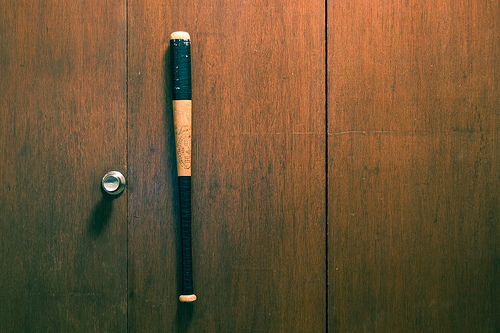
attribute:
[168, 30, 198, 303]
baseball — wooden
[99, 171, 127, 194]
object — metal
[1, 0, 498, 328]
table — wooden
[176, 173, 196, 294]
tape — black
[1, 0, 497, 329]
wall — wood panelling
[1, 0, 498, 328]
wood — burned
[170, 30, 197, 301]
wood — stamped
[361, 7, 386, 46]
specks — brown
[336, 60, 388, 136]
specks — brown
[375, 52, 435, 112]
specks — brown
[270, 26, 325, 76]
specks — brown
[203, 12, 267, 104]
specks — brown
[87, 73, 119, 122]
specks — brown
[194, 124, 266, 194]
specks — brown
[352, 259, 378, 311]
strike — black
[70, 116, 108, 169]
strike — black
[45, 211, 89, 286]
strike — black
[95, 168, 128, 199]
doorknob — silver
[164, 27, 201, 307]
bat — wooden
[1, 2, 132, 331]
door — dark, wood grain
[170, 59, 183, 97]
specs — white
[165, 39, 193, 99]
tape — black